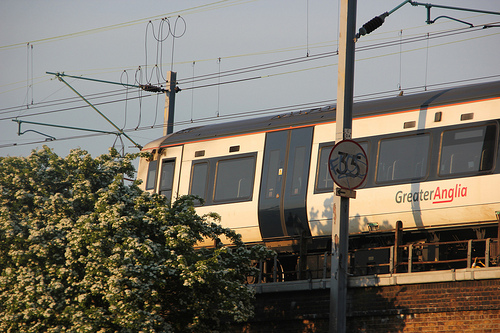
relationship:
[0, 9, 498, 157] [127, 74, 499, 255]
wireline above train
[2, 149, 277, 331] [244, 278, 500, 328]
bush on wall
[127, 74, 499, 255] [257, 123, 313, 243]
train has door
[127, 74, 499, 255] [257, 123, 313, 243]
train has doors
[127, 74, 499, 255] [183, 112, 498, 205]
train has window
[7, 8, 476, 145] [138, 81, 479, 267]
power lines for train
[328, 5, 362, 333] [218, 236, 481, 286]
pole along tracks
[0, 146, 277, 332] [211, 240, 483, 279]
bush on side of tracks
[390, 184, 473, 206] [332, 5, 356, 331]
sign on pole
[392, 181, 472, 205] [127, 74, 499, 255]
writing on train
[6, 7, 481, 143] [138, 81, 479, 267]
wires above train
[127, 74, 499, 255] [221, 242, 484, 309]
train on tracks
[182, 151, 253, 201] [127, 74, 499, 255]
window on side of train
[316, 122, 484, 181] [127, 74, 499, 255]
window on side of train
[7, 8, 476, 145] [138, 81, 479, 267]
power lines above train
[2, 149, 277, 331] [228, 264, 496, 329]
bush inf front of wall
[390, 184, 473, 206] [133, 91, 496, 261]
sign on train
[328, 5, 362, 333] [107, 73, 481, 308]
pole on side of train